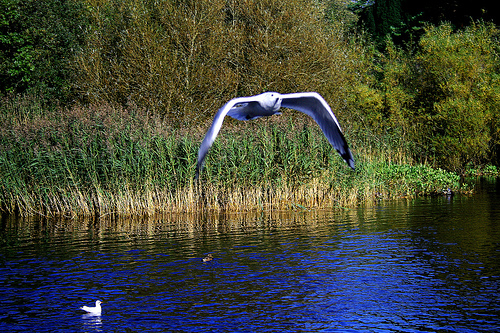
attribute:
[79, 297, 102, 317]
bird — white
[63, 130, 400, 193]
grass — green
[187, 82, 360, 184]
bird — moving, horizontal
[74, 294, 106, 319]
bird — white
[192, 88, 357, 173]
bird — air, white, flying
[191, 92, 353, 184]
sea gull — white, swimming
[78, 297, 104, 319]
sea gull — white, swimming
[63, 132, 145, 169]
grass — green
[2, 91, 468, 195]
plants — green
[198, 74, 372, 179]
bird — swimming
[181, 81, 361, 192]
gull — white, seagull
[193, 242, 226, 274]
gull — seagull, white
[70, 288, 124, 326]
gull — seagull, white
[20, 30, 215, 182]
foliage — green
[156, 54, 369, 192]
sea gull — airborne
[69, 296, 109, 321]
bird — swimming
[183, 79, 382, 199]
bird — white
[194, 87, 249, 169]
wing — folded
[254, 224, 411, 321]
water — blue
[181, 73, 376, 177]
bird — blue, white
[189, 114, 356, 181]
wings — open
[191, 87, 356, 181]
bird — white, airborne, flying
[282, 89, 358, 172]
wing — white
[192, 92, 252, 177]
wing — white